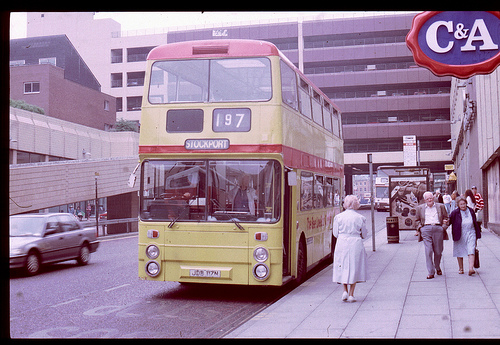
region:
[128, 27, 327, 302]
Red and yellow bus on the street.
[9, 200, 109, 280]
Silver car on the road.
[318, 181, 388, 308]
Woman in a white jacket on the sidewalk.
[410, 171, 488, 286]
A man and woman walking down the sidewalk.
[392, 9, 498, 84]
Red, blue and white sign hanging on a building.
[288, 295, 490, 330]
A downtown city sidewalk.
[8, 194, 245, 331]
A busy street in a downtown area.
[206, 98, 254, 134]
Sign on a bus that shows the number 197.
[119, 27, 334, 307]
A double-decker yellow bus.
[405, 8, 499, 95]
Blue and red sign with white letters.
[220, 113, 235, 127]
The number 9 on the front of the bus.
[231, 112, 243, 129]
The number 7 on the front of the bus.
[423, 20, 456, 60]
The letter C on the building sign.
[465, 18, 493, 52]
The letter A on the building sign.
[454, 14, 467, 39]
The & symbol on the business sign.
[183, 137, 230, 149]
The marquee with the destination location.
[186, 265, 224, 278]
The white license plate on the front of the bus.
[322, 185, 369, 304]
The lady walking with white shoes on.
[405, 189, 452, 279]
The man walking with the older lady.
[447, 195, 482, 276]
The older lady with a black jacket on.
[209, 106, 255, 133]
a number on the front of the bus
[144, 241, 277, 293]
four shiny headlights on the bus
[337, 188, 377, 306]
a woman walking to the bus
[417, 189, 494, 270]
an elderly couple walking down the sidwalk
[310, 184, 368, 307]
a woman with white hair wearing a white dress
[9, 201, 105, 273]
a silver car driving down the street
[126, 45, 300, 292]
a yellow and red double decker bus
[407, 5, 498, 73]
a red and blue sign with white letter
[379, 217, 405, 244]
a metal trash can on the sidewalk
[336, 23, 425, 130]
a large parking deck behind the bus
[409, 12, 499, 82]
a round business sign in blue, red and white with the letters C & A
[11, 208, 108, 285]
a small car driving past on the street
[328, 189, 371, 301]
an old lady in a white coat walking on the side walk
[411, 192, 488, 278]
an elderly couple walking on the sidewalk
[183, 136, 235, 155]
a sign on the front of the bus that says Stockport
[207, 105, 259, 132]
the number of the bus that says 197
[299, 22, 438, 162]
a large parking garage in the background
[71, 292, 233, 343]
faded words painted in the street that say stop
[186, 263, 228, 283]
the license plate on the bus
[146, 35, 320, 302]
a yellow double decker bus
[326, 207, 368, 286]
the woman has on a white dress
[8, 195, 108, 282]
a small silver sedan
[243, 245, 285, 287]
the headlight of the bus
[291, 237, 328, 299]
the tire of the bus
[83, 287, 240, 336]
the word stop painted on the street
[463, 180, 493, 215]
the man wears a red and white shirt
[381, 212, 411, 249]
a trash can by the bus stop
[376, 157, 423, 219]
a bus in the distance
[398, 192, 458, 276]
man walking with his hands in pockets